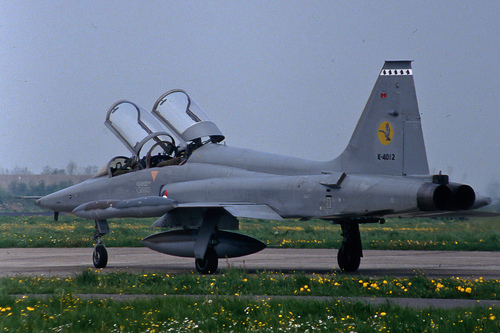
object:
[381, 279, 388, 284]
flower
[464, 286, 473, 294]
flower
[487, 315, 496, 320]
flower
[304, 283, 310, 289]
flower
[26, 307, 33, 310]
flower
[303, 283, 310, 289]
flowers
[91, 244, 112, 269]
wheel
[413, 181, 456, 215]
exhaust pipes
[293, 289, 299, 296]
flowers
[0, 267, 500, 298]
green grass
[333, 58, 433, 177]
tail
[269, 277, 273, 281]
flowers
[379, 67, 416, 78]
design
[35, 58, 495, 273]
airplane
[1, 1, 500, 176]
sky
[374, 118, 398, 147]
design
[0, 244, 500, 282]
runway